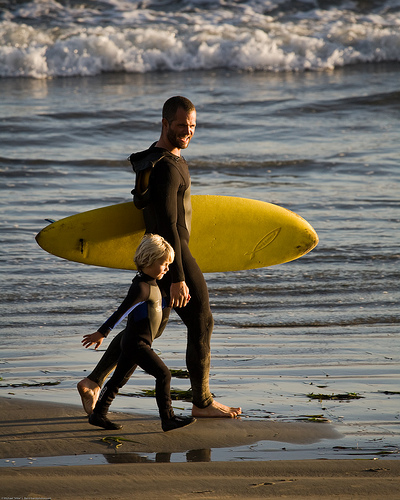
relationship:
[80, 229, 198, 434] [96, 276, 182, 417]
boy wearing wet suit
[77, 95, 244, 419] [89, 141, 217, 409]
man wearing wet suit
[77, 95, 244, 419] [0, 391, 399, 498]
man on sand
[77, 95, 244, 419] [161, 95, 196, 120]
man has hair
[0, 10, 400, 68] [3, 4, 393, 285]
wave in water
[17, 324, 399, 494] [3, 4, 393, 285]
sand next to water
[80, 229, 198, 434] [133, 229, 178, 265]
boy has hair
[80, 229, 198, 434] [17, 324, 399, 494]
boy on sand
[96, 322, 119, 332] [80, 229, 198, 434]
stripe on boy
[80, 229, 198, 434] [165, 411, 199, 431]
boy wearing shoe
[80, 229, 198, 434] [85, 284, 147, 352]
boy has arm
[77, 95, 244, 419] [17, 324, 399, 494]
man on sand